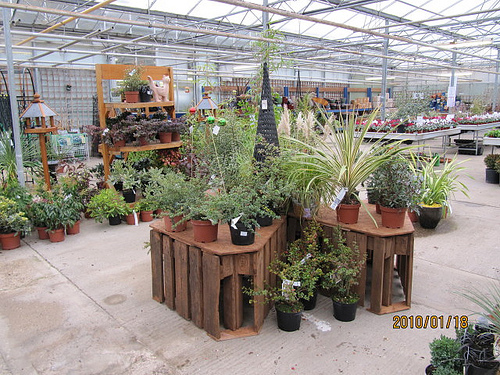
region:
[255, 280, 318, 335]
this is a flower pot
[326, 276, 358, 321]
this is a flower pot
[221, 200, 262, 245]
this is a flower pot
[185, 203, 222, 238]
this is a flower pot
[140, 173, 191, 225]
this is a flower pot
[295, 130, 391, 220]
this is a flower pot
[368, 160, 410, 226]
this is a flower pot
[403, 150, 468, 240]
this is a flower pot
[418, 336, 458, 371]
this is a flower pot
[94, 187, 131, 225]
this is a flower pot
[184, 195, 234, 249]
The pot is colored clay.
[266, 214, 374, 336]
three green leafy plants are on the ground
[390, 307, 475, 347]
The picture has a date stamp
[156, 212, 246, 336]
The stand is made from wood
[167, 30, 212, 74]
The ceiling is made from metal piping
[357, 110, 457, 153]
the flowers are sitting on a gray table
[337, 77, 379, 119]
Blue shelving hold empty flower pots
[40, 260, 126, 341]
The floor is gray concrete.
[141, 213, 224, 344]
the plant shelf has brown vertical slats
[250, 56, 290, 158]
A green wire cones sits in the middle of the plants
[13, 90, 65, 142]
a gazebo like structure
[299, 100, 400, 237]
a palm like plant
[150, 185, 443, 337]
a pair of wooden tables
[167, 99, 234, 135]
a few decorative balls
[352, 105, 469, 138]
a display of flowering plants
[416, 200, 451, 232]
a large black pot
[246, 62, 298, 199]
a black cone like structure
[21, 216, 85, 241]
a few terra cotta plants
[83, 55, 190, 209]
a few wooden shelves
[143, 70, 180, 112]
pot shaped like a cat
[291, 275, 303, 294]
part of a flower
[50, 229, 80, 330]
part of a floor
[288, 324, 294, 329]
bottom of a vase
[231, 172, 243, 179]
leaf of a plant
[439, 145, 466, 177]
part of a table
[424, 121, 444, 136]
edge of a table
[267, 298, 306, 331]
a flower vase in the picture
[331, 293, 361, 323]
a flower vase in the picture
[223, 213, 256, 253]
a flower vase in the picture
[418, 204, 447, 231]
a flower vase in the picture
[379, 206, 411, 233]
a flower vase in the picture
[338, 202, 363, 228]
a flower vase in the picture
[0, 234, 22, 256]
a flower vase in the picture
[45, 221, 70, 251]
a flower vase in the picture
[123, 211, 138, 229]
a flower vase in the picture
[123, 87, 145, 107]
a flower vase in the picture